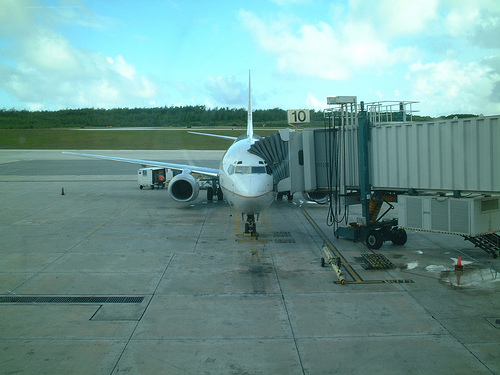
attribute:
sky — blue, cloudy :
[0, 4, 499, 119]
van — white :
[124, 153, 226, 207]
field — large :
[46, 127, 185, 154]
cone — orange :
[453, 250, 463, 267]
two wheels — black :
[364, 228, 406, 249]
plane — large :
[64, 70, 296, 229]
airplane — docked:
[60, 67, 281, 236]